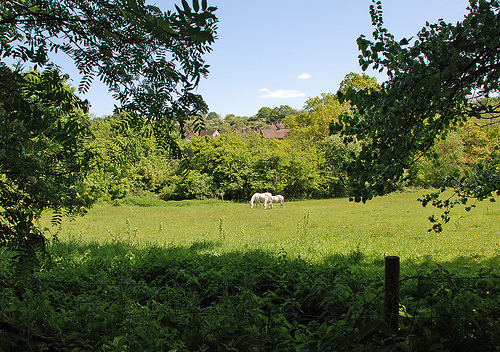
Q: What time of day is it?
A: Daytime.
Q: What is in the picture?
A: Horses.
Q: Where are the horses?
A: In a field.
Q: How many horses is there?
A: Two.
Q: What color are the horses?
A: White.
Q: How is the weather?
A: Nice.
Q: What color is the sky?
A: Blue.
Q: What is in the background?
A: Trees and rooftops.